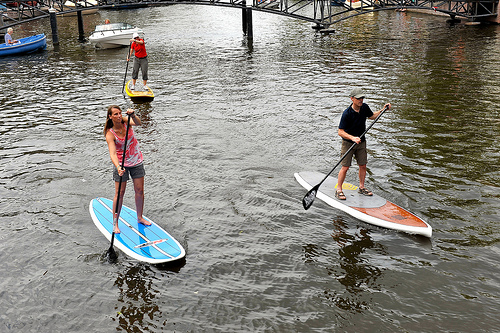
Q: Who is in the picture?
A: Five people.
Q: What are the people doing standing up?
A: Paddle boarding.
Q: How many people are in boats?
A: Two.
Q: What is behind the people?
A: A bridge.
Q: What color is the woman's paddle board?
A: Blue and white.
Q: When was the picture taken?
A: At daytime.